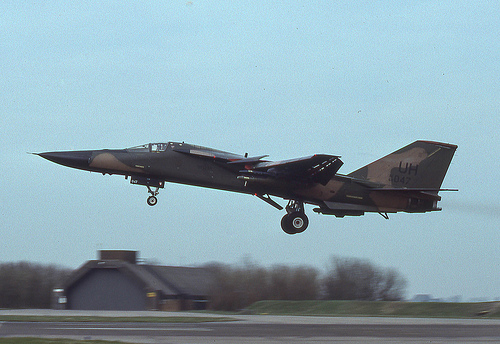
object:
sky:
[0, 0, 499, 300]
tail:
[344, 139, 459, 186]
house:
[50, 248, 234, 311]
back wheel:
[283, 213, 310, 235]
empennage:
[346, 139, 459, 192]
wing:
[227, 153, 272, 168]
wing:
[256, 153, 343, 188]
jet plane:
[26, 139, 463, 236]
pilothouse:
[122, 141, 179, 152]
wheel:
[277, 214, 299, 235]